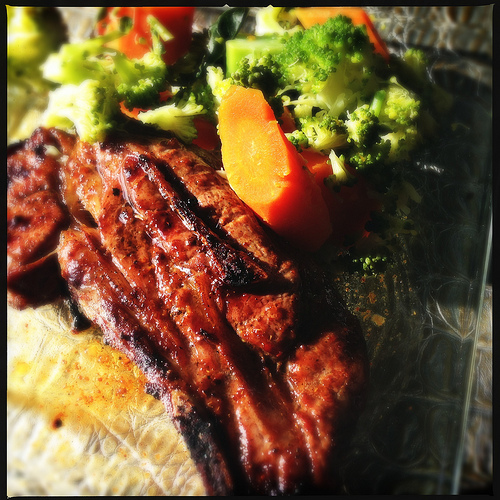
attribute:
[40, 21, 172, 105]
broccoli — green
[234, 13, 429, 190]
broccoli — green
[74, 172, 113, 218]
color — tan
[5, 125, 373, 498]
meat — tan color, black, red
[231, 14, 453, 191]
broccoli — green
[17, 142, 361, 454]
meat — burnt, black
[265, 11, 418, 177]
broccoli — green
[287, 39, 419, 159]
broccoli — green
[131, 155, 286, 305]
meat — burnt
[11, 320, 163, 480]
surface — orange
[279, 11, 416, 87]
carrots — chopped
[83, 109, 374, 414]
meat — burnt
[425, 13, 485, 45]
plate — blurry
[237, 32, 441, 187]
broccoli — dark green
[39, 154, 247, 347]
meat — tan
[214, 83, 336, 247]
carrot — dark orange, orange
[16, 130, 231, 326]
chicken breast — seared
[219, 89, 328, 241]
carrot — orange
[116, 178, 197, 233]
chicken — juicy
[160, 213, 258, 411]
meat — red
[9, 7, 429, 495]
meal — delicious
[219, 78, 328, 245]
carrot slice — orange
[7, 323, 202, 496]
stain — orange , greasy 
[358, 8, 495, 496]
background — silver